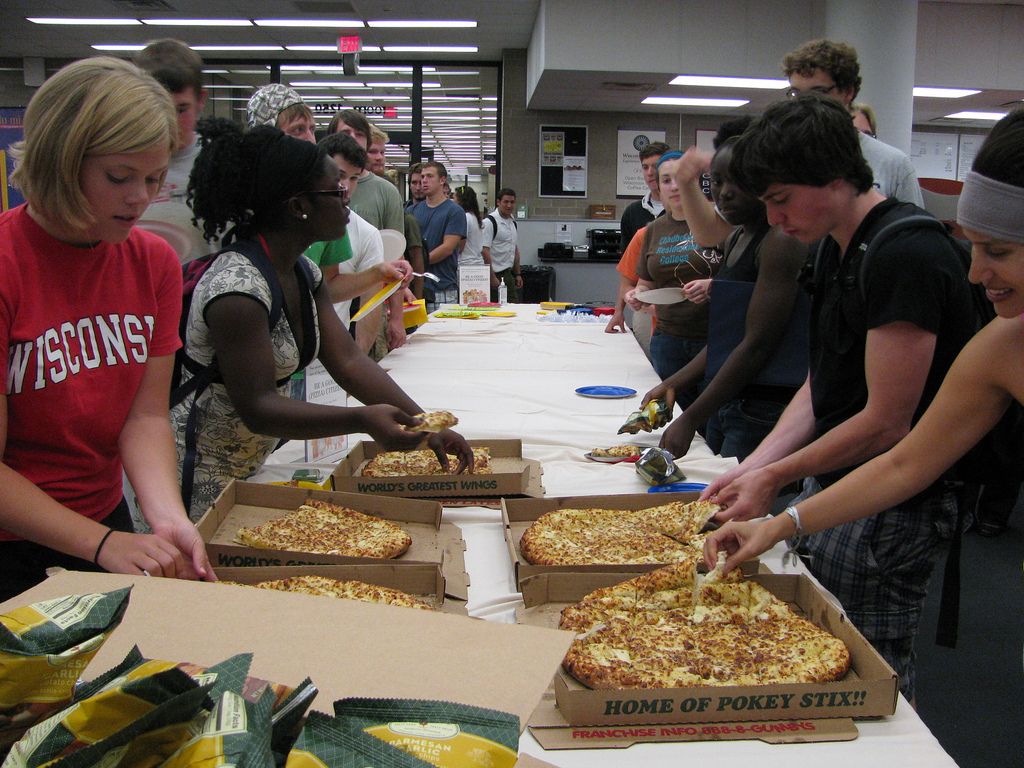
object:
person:
[0, 56, 221, 608]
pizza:
[233, 411, 854, 689]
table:
[76, 302, 955, 765]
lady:
[699, 102, 1024, 572]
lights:
[27, 17, 496, 192]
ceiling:
[0, 1, 1024, 111]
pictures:
[537, 123, 586, 199]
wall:
[499, 46, 759, 302]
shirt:
[0, 203, 183, 543]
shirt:
[302, 226, 352, 267]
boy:
[299, 132, 412, 305]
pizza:
[559, 551, 850, 690]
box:
[509, 571, 900, 749]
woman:
[134, 113, 474, 530]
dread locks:
[187, 115, 327, 246]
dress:
[131, 252, 322, 534]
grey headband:
[955, 171, 1024, 245]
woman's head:
[955, 105, 1024, 319]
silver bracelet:
[781, 507, 816, 568]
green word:
[799, 690, 868, 707]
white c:
[60, 321, 82, 374]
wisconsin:
[5, 314, 153, 397]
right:
[603, 226, 647, 334]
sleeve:
[616, 226, 646, 282]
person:
[624, 151, 726, 409]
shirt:
[633, 211, 724, 340]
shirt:
[482, 207, 518, 274]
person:
[480, 188, 521, 304]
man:
[699, 90, 990, 713]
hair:
[726, 93, 874, 201]